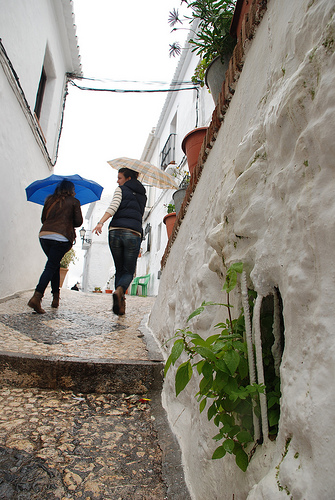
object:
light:
[79, 227, 86, 243]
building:
[78, 186, 113, 293]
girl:
[37, 184, 87, 270]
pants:
[108, 228, 141, 291]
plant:
[167, 257, 286, 456]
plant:
[167, 1, 239, 86]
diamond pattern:
[0, 309, 130, 347]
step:
[3, 355, 165, 388]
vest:
[109, 178, 147, 233]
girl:
[91, 168, 147, 314]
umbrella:
[25, 173, 102, 204]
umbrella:
[107, 156, 179, 191]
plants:
[163, 263, 280, 472]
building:
[0, 0, 82, 242]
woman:
[112, 169, 149, 220]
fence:
[159, 133, 176, 171]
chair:
[130, 273, 151, 296]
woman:
[86, 155, 175, 280]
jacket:
[107, 180, 147, 234]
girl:
[37, 181, 83, 245]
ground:
[301, 80, 308, 88]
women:
[27, 178, 83, 313]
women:
[92, 167, 139, 314]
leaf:
[138, 398, 151, 402]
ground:
[1, 384, 170, 498]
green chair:
[130, 273, 150, 297]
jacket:
[37, 190, 83, 242]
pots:
[205, 53, 233, 107]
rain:
[2, 0, 334, 498]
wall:
[147, 58, 335, 500]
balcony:
[158, 133, 175, 171]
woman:
[27, 177, 84, 312]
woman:
[90, 166, 147, 314]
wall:
[149, 1, 335, 498]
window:
[32, 40, 58, 133]